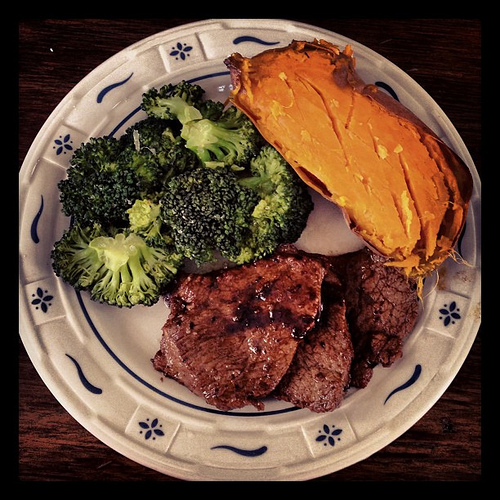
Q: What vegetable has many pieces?
A: Broccoli.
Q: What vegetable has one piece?
A: Sweet potato.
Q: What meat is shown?
A: Steak.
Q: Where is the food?
A: On plate.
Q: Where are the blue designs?
A: On plate.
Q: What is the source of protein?
A: Meat.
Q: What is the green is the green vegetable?
A: Broccoli.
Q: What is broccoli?
A: A vegetable.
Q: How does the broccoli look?
A: Green and fresh.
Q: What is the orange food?
A: Sweet potato.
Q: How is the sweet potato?
A: Baked.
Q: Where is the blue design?
A: On a white plate.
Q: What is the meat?
A: Steak.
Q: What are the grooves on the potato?
A: Scoring marks.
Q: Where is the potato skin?
A: On half of the potato.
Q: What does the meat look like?
A: Beef steak.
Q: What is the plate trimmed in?
A: Blue.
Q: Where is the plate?
A: Table.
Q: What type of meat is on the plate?
A: Beef.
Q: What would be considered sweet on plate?
A: Potato.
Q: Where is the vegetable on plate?
A: Middle.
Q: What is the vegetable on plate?
A: Broccoli.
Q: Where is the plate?
A: On the table.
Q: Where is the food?
A: On the plate.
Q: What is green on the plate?
A: Broccoli.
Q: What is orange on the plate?
A: Sweet potato.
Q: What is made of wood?
A: The table.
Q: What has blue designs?
A: The plate.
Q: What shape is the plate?
A: Circular.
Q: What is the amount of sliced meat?
A: Three.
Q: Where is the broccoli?
A: Left of plate.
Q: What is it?
A: Food.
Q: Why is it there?
A: To eat.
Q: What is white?
A: Plate.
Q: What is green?
A: The broccoli.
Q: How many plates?
A: 1.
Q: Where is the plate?
A: On the table.